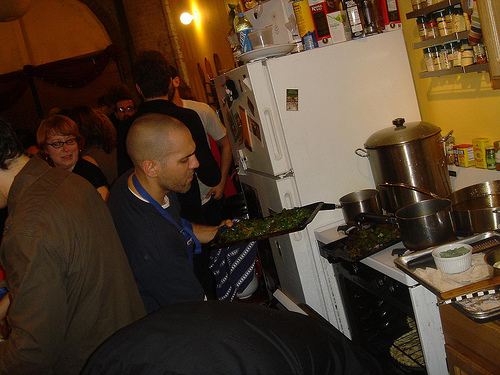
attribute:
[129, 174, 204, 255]
lanyard — blue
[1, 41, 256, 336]
group — people